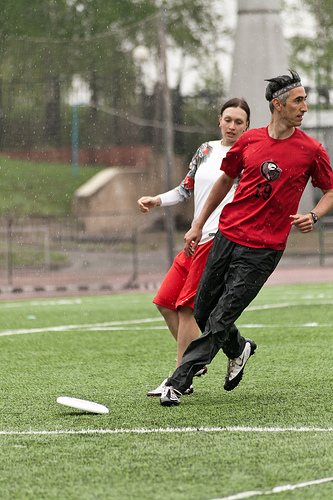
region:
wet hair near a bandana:
[260, 67, 308, 104]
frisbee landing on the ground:
[44, 380, 119, 434]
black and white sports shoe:
[206, 330, 270, 399]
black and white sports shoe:
[156, 375, 197, 416]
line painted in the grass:
[0, 419, 332, 451]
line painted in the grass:
[195, 466, 332, 497]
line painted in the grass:
[65, 314, 331, 342]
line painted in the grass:
[0, 289, 325, 348]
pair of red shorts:
[139, 224, 230, 321]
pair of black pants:
[156, 227, 295, 400]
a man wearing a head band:
[248, 70, 312, 148]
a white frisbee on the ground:
[59, 386, 120, 425]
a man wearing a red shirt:
[221, 80, 314, 276]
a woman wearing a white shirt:
[168, 92, 246, 240]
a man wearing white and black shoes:
[141, 328, 255, 436]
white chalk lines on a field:
[4, 421, 288, 474]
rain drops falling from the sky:
[47, 52, 202, 180]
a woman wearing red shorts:
[165, 53, 252, 323]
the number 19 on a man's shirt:
[246, 152, 296, 238]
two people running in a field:
[129, 44, 331, 325]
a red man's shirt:
[211, 113, 331, 254]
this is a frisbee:
[56, 389, 112, 421]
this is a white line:
[1, 422, 325, 439]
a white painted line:
[13, 321, 143, 354]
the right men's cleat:
[220, 330, 265, 397]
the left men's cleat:
[154, 372, 187, 418]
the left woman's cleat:
[140, 372, 213, 410]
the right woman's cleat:
[152, 346, 213, 390]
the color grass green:
[156, 432, 194, 465]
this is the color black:
[204, 346, 210, 353]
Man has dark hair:
[257, 64, 315, 115]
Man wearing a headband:
[260, 78, 325, 97]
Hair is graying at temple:
[259, 64, 313, 110]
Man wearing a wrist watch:
[308, 200, 323, 232]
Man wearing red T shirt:
[218, 108, 325, 261]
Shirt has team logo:
[247, 150, 288, 220]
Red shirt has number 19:
[245, 177, 285, 209]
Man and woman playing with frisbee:
[53, 58, 324, 479]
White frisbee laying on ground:
[40, 372, 110, 427]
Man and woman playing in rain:
[43, 47, 332, 290]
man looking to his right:
[268, 77, 318, 130]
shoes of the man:
[143, 332, 273, 429]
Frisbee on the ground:
[63, 365, 117, 430]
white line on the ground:
[183, 408, 237, 450]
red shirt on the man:
[219, 132, 321, 223]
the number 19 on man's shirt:
[239, 173, 280, 208]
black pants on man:
[162, 236, 286, 347]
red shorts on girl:
[151, 236, 213, 298]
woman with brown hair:
[218, 100, 256, 122]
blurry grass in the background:
[21, 165, 65, 200]